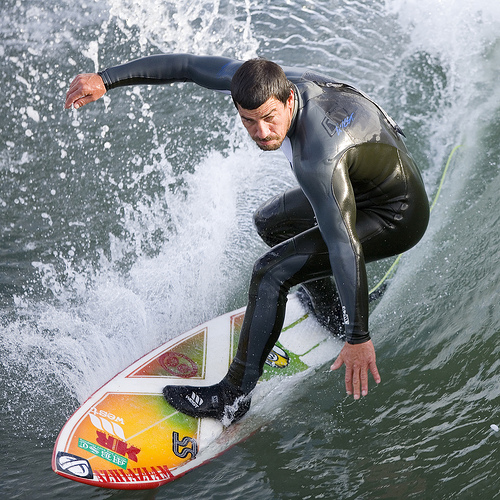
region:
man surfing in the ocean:
[46, 41, 449, 452]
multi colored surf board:
[41, 310, 323, 497]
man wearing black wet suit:
[176, 51, 477, 379]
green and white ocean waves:
[303, 415, 404, 475]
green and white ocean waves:
[39, 283, 127, 343]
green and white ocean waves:
[103, 230, 195, 291]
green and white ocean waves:
[154, 183, 234, 273]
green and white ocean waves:
[8, 154, 141, 238]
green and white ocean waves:
[14, 19, 83, 61]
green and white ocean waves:
[330, 29, 436, 76]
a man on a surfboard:
[43, 50, 435, 489]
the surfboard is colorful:
[50, 273, 375, 493]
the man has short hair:
[225, 58, 303, 153]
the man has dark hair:
[222, 50, 298, 156]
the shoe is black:
[159, 376, 255, 421]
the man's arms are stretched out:
[49, 33, 436, 425]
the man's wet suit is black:
[100, 37, 434, 414]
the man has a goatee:
[253, 128, 282, 153]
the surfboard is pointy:
[50, 290, 370, 489]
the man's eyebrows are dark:
[238, 103, 278, 123]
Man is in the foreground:
[60, 43, 443, 425]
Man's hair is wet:
[220, 49, 302, 154]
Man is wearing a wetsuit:
[50, 46, 445, 430]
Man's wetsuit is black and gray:
[41, 37, 438, 436]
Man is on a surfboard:
[34, 255, 410, 492]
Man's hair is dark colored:
[206, 50, 307, 151]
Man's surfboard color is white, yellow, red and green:
[46, 273, 396, 498]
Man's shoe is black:
[160, 373, 262, 423]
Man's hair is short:
[209, 56, 306, 128]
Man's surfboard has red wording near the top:
[63, 426, 195, 491]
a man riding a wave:
[48, 55, 435, 487]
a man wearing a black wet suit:
[99, 55, 430, 425]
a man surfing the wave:
[53, 60, 430, 484]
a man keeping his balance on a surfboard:
[52, 54, 434, 486]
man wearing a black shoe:
[163, 382, 246, 421]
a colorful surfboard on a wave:
[34, 285, 369, 488]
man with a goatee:
[251, 129, 284, 150]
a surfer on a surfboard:
[52, 50, 432, 487]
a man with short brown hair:
[228, 62, 297, 152]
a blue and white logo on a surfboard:
[56, 450, 93, 477]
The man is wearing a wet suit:
[69, 52, 433, 428]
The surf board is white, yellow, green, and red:
[35, 280, 333, 490]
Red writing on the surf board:
[82, 446, 169, 487]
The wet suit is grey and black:
[67, 42, 443, 433]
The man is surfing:
[54, 34, 414, 476]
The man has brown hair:
[233, 63, 302, 155]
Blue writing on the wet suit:
[326, 103, 362, 139]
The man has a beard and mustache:
[223, 58, 303, 153]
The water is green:
[342, 192, 484, 446]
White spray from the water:
[36, 81, 417, 488]